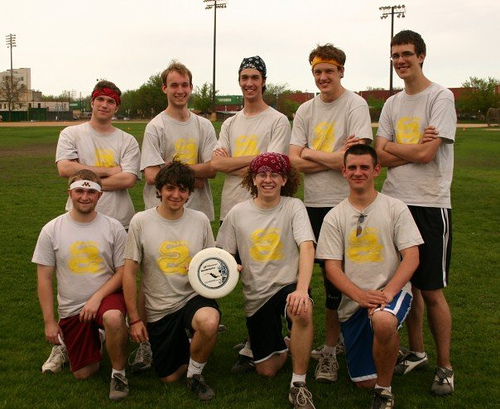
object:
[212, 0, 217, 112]
pole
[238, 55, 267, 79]
band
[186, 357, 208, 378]
socks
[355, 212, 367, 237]
sunglasses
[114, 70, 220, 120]
trees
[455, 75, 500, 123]
trees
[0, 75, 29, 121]
trees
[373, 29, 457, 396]
man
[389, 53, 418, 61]
glasses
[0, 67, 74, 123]
building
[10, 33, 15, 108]
pole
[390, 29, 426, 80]
head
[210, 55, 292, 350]
green guy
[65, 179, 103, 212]
sweatband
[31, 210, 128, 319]
t-shirt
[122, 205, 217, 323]
t-shirt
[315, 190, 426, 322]
t-shirt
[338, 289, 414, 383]
shorts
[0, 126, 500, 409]
field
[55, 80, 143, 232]
man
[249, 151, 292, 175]
bandana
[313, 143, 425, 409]
boys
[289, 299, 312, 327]
knee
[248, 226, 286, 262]
writing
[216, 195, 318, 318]
shirt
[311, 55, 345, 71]
headband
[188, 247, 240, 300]
frisbee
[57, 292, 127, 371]
shorts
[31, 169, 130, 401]
man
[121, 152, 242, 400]
man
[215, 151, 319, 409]
man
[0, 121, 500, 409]
lawn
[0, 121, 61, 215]
ground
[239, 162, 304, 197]
hair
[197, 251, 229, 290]
markings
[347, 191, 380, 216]
collar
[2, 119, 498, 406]
grass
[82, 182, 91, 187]
letter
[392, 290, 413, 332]
stripes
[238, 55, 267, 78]
bandana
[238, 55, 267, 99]
head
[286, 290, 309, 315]
hand